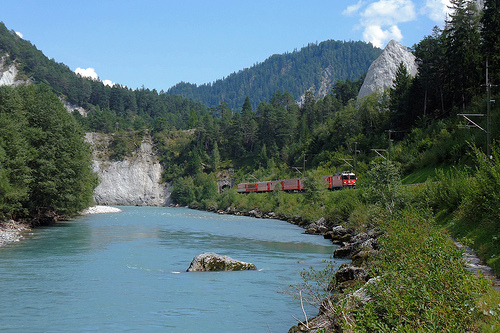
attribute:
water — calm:
[40, 226, 254, 321]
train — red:
[227, 148, 388, 210]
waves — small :
[111, 220, 234, 255]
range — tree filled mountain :
[7, 19, 483, 323]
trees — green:
[5, 80, 97, 225]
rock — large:
[182, 240, 256, 282]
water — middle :
[43, 245, 169, 325]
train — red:
[224, 165, 363, 195]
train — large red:
[236, 166, 357, 201]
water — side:
[45, 250, 186, 319]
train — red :
[233, 162, 368, 196]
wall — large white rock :
[96, 142, 161, 220]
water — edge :
[12, 197, 312, 328]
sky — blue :
[80, 13, 217, 47]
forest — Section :
[220, 93, 450, 186]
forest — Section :
[285, 85, 469, 177]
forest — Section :
[210, 90, 420, 170]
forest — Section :
[354, 99, 458, 167]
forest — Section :
[391, 123, 468, 220]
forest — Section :
[400, 111, 468, 206]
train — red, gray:
[211, 166, 361, 193]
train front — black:
[330, 166, 362, 187]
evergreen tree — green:
[19, 70, 100, 234]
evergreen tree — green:
[1, 72, 39, 231]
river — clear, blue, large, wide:
[1, 195, 343, 329]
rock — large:
[184, 250, 265, 276]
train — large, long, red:
[214, 168, 365, 197]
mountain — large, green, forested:
[147, 34, 406, 117]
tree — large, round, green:
[30, 77, 102, 231]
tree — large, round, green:
[1, 73, 39, 238]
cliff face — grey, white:
[85, 129, 177, 211]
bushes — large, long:
[316, 202, 493, 332]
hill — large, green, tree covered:
[1, 20, 205, 151]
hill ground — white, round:
[78, 202, 128, 222]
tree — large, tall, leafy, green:
[0, 84, 33, 221]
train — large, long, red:
[234, 172, 359, 192]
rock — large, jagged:
[187, 250, 259, 270]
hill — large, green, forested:
[178, 81, 350, 171]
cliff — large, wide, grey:
[92, 132, 164, 205]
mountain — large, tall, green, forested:
[159, 38, 383, 109]